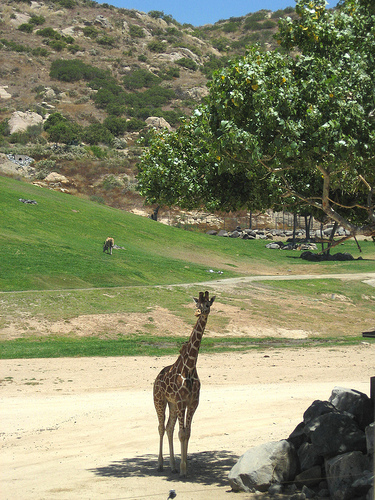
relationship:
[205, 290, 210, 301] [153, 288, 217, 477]
horn on giraffe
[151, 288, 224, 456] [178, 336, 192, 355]
giraffe has spot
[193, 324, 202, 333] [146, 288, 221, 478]
brown spot on giraffe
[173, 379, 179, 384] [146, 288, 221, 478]
brown spot on giraffe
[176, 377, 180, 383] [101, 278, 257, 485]
brown spot on giraffe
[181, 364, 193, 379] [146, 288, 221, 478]
brown spot on giraffe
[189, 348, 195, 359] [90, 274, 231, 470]
brown spot on giraffe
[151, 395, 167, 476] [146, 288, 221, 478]
leg of giraffe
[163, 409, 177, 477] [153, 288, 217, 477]
leg of giraffe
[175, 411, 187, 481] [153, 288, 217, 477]
giraffe's leg of giraffe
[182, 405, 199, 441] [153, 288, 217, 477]
giraffe's leg of giraffe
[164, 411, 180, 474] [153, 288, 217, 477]
giraffe's leg of giraffe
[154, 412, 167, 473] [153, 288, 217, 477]
giraffe's leg of giraffe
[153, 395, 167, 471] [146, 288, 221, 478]
leg of giraffe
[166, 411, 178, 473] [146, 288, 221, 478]
leg of giraffe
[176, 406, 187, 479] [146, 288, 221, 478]
leg of giraffe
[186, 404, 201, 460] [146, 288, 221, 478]
leg of giraffe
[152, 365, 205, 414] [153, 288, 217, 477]
body of giraffe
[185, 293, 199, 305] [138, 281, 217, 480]
ear of giraffe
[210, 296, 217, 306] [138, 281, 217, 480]
ear of giraffe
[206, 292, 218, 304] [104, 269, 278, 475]
ear of giraffe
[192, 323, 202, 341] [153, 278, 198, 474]
neck of giraffe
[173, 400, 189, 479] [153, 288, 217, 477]
leg of giraffe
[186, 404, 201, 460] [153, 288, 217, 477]
leg of giraffe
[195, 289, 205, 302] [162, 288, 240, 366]
horn of giraffe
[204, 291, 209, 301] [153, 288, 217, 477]
horn of giraffe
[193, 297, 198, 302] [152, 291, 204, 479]
ear of giraffe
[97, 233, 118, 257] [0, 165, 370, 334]
animal eating grass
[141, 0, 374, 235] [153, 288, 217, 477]
tree to right of giraffe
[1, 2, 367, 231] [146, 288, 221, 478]
hills behind giraffe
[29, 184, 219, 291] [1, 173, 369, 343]
grass on hill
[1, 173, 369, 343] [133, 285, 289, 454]
hill behind giraffe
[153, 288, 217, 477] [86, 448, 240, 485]
giraffe standing in shade